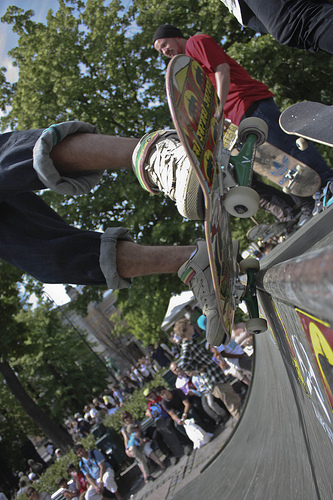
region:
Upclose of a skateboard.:
[165, 52, 268, 336]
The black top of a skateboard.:
[277, 101, 331, 151]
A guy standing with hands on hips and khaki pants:
[169, 317, 243, 420]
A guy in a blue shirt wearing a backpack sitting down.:
[71, 444, 119, 499]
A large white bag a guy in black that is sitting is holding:
[178, 417, 215, 452]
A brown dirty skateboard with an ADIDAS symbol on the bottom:
[217, 121, 320, 198]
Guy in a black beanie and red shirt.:
[149, 27, 331, 225]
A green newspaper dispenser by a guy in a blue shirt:
[87, 423, 130, 471]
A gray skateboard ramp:
[176, 207, 331, 498]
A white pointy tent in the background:
[159, 290, 197, 330]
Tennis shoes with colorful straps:
[129, 128, 224, 347]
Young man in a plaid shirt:
[173, 315, 239, 418]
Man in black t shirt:
[154, 383, 207, 443]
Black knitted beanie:
[149, 23, 182, 45]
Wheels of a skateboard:
[222, 116, 269, 336]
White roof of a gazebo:
[157, 289, 196, 333]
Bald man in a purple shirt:
[167, 360, 190, 394]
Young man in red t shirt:
[151, 22, 332, 183]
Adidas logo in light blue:
[267, 155, 301, 186]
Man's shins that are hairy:
[49, 131, 195, 278]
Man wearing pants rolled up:
[13, 100, 117, 292]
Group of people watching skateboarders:
[36, 385, 235, 488]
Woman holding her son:
[112, 395, 190, 490]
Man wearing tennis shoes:
[107, 130, 227, 285]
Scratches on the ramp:
[238, 394, 305, 470]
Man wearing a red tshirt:
[150, 13, 318, 146]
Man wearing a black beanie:
[145, 12, 197, 60]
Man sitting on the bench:
[69, 444, 111, 487]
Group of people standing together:
[37, 382, 173, 430]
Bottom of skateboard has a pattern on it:
[151, 57, 267, 231]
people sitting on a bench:
[104, 362, 225, 474]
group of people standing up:
[61, 349, 164, 435]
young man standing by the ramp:
[160, 321, 275, 432]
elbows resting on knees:
[160, 401, 202, 422]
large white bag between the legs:
[167, 414, 219, 453]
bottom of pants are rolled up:
[86, 224, 150, 300]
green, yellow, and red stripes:
[174, 266, 199, 291]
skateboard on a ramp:
[138, 50, 313, 368]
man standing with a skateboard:
[134, 22, 332, 213]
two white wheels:
[224, 111, 277, 229]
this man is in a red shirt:
[156, 26, 293, 140]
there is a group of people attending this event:
[35, 327, 218, 453]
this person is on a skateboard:
[146, 49, 267, 351]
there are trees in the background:
[19, 21, 152, 119]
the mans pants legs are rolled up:
[29, 114, 139, 322]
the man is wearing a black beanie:
[130, 23, 188, 49]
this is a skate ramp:
[224, 304, 331, 479]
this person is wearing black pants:
[239, 7, 323, 61]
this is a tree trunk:
[2, 381, 71, 454]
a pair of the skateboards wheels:
[220, 119, 270, 221]